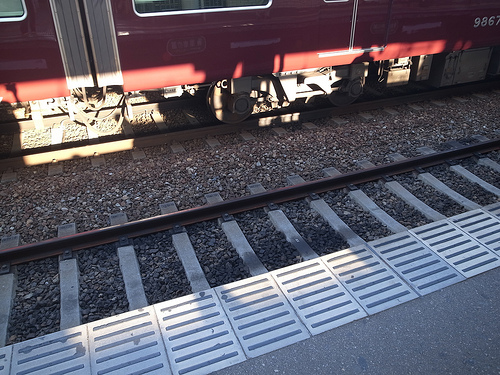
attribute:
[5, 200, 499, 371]
rectangles — silver, tiles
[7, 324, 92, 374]
tile — metal, rectangular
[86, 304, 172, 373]
tile — metal, rectangular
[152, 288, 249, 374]
tile — rectangular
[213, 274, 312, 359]
tile — rectangular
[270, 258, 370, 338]
tile — rectangular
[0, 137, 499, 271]
rail — empty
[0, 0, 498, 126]
train — red, white, passenger train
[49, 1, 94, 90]
panel — gray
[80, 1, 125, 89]
panel — gray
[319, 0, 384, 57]
line — white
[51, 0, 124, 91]
connector — gray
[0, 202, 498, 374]
platform — paved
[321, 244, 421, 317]
tile — metal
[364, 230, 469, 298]
tile — metal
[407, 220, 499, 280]
tile — metal